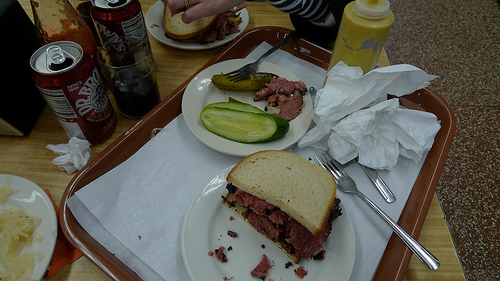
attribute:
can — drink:
[87, 1, 153, 77]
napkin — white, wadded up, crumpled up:
[298, 60, 441, 148]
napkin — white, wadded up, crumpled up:
[325, 98, 443, 171]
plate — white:
[180, 59, 312, 156]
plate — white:
[180, 167, 357, 279]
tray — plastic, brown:
[59, 26, 453, 280]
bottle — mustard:
[327, 0, 397, 69]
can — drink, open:
[28, 40, 118, 144]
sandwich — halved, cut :
[220, 148, 342, 263]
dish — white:
[180, 163, 358, 280]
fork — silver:
[313, 150, 442, 272]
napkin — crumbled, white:
[308, 53, 453, 187]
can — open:
[19, 34, 131, 152]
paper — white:
[37, 124, 102, 180]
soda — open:
[24, 36, 107, 152]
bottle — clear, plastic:
[326, 2, 400, 83]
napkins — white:
[293, 51, 451, 178]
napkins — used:
[42, 127, 96, 170]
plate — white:
[4, 165, 62, 279]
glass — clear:
[88, 24, 171, 127]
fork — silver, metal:
[315, 144, 440, 280]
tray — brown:
[50, 16, 470, 279]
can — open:
[15, 27, 125, 152]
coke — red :
[30, 39, 118, 149]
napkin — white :
[305, 62, 443, 169]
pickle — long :
[202, 104, 291, 147]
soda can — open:
[26, 38, 118, 146]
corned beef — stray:
[251, 74, 307, 100]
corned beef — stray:
[267, 90, 305, 120]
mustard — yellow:
[320, 0, 396, 86]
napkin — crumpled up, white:
[43, 136, 92, 176]